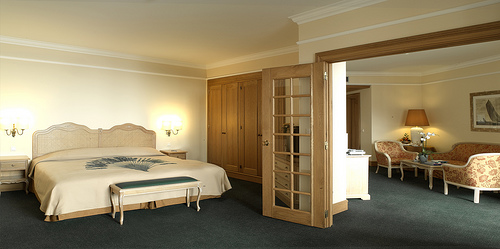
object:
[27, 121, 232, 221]
bed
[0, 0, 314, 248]
bedroom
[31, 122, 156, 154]
headboard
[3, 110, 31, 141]
light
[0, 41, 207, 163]
wall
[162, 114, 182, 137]
light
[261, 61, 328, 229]
door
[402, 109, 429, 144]
lamp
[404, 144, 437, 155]
table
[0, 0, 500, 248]
room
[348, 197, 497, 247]
floor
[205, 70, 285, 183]
closet doors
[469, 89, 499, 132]
painting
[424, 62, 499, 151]
wall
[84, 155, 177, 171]
design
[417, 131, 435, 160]
flowers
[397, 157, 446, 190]
table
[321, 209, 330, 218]
hinges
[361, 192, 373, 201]
foot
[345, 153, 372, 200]
dresser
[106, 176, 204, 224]
bench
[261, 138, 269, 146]
handle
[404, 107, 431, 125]
lampshade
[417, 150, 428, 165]
vase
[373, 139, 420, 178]
chair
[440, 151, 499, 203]
chair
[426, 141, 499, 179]
couch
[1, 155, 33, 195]
nightstand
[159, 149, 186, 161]
nightstand